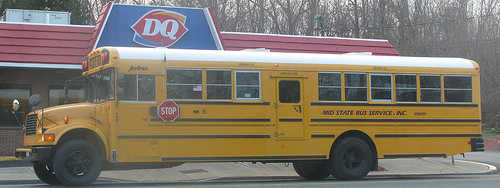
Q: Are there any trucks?
A: No, there are no trucks.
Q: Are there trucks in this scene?
A: No, there are no trucks.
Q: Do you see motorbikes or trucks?
A: No, there are no trucks or motorbikes.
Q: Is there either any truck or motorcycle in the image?
A: No, there are no trucks or motorcycles.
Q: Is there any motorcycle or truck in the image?
A: No, there are no trucks or motorcycles.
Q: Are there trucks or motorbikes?
A: No, there are no trucks or motorbikes.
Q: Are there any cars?
A: No, there are no cars.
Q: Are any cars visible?
A: No, there are no cars.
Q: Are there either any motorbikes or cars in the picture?
A: No, there are no cars or motorbikes.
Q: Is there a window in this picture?
A: Yes, there are windows.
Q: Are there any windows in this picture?
A: Yes, there are windows.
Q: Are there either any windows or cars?
A: Yes, there are windows.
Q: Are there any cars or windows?
A: Yes, there are windows.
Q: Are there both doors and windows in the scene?
A: Yes, there are both windows and a door.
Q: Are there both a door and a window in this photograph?
A: Yes, there are both a window and a door.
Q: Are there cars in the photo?
A: No, there are no cars.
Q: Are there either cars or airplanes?
A: No, there are no cars or airplanes.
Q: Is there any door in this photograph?
A: Yes, there is a door.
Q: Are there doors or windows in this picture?
A: Yes, there is a door.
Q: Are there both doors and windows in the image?
A: Yes, there are both a door and a window.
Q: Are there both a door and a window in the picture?
A: Yes, there are both a door and a window.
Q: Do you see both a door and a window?
A: Yes, there are both a door and a window.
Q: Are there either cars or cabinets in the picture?
A: No, there are no cars or cabinets.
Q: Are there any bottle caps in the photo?
A: No, there are no bottle caps.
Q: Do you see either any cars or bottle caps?
A: No, there are no bottle caps or cars.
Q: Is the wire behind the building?
A: Yes, the wire is behind the building.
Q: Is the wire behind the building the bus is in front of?
A: Yes, the wire is behind the building.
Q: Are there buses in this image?
A: Yes, there is a bus.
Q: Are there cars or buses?
A: Yes, there is a bus.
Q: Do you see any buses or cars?
A: Yes, there is a bus.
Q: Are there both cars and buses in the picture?
A: No, there is a bus but no cars.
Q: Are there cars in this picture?
A: No, there are no cars.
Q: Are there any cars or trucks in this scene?
A: No, there are no cars or trucks.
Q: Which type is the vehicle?
A: The vehicle is a bus.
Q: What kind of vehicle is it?
A: The vehicle is a bus.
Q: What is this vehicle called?
A: This is a bus.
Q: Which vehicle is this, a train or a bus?
A: This is a bus.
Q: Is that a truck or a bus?
A: That is a bus.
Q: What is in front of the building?
A: The bus is in front of the building.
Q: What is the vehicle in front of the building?
A: The vehicle is a bus.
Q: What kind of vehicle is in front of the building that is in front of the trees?
A: The vehicle is a bus.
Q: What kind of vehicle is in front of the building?
A: The vehicle is a bus.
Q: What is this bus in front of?
A: The bus is in front of the building.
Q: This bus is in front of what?
A: The bus is in front of the building.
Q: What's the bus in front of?
A: The bus is in front of the building.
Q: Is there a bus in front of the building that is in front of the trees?
A: Yes, there is a bus in front of the building.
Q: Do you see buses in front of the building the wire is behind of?
A: Yes, there is a bus in front of the building.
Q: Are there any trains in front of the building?
A: No, there is a bus in front of the building.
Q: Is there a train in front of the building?
A: No, there is a bus in front of the building.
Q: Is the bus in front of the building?
A: Yes, the bus is in front of the building.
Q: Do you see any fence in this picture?
A: No, there are no fences.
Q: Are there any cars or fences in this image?
A: No, there are no fences or cars.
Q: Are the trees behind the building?
A: Yes, the trees are behind the building.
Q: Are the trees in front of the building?
A: No, the trees are behind the building.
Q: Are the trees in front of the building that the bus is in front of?
A: No, the trees are behind the building.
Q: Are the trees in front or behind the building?
A: The trees are behind the building.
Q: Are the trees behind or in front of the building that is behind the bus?
A: The trees are behind the building.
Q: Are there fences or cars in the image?
A: No, there are no cars or fences.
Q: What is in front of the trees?
A: The building is in front of the trees.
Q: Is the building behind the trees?
A: No, the building is in front of the trees.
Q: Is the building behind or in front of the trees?
A: The building is in front of the trees.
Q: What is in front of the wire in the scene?
A: The building is in front of the wire.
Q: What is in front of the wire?
A: The building is in front of the wire.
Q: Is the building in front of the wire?
A: Yes, the building is in front of the wire.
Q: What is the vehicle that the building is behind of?
A: The vehicle is a bus.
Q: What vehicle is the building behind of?
A: The building is behind the bus.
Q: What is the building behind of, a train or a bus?
A: The building is behind a bus.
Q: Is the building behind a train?
A: No, the building is behind the bus.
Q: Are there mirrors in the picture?
A: Yes, there is a mirror.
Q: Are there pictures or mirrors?
A: Yes, there is a mirror.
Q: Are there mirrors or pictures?
A: Yes, there is a mirror.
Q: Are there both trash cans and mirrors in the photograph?
A: No, there is a mirror but no trash cans.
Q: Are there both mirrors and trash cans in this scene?
A: No, there is a mirror but no trash cans.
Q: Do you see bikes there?
A: No, there are no bikes.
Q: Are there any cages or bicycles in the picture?
A: No, there are no bicycles or cages.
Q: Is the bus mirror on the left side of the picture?
A: Yes, the mirror is on the left of the image.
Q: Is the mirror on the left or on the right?
A: The mirror is on the left of the image.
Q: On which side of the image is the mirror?
A: The mirror is on the left of the image.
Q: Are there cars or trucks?
A: No, there are no cars or trucks.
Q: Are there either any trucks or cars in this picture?
A: No, there are no cars or trucks.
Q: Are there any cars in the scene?
A: No, there are no cars.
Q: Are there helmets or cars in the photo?
A: No, there are no cars or helmets.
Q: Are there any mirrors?
A: Yes, there is a mirror.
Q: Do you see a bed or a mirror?
A: Yes, there is a mirror.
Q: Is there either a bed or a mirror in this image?
A: Yes, there is a mirror.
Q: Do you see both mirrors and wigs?
A: No, there is a mirror but no wigs.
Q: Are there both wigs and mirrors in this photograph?
A: No, there is a mirror but no wigs.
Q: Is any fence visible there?
A: No, there are no fences.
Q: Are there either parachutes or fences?
A: No, there are no fences or parachutes.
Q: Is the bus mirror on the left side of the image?
A: Yes, the mirror is on the left of the image.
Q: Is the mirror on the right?
A: No, the mirror is on the left of the image.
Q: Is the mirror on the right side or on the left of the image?
A: The mirror is on the left of the image.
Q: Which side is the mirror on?
A: The mirror is on the left of the image.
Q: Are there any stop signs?
A: Yes, there is a stop sign.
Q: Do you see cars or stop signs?
A: Yes, there is a stop sign.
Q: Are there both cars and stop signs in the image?
A: No, there is a stop sign but no cars.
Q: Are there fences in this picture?
A: No, there are no fences.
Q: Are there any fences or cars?
A: No, there are no fences or cars.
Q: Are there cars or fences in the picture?
A: No, there are no fences or cars.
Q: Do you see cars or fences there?
A: No, there are no fences or cars.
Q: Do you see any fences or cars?
A: No, there are no fences or cars.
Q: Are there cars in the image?
A: No, there are no cars.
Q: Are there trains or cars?
A: No, there are no cars or trains.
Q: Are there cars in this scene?
A: No, there are no cars.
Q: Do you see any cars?
A: No, there are no cars.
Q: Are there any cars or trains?
A: No, there are no cars or trains.